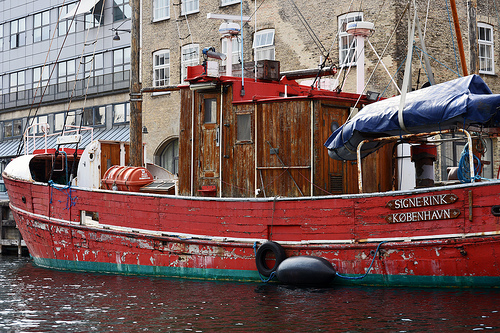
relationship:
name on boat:
[385, 193, 459, 210] [2, 46, 471, 296]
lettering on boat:
[389, 206, 455, 224] [0, 58, 499, 270]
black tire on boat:
[254, 240, 287, 278] [0, 58, 499, 270]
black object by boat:
[276, 255, 337, 288] [0, 58, 499, 270]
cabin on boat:
[177, 59, 396, 197] [0, 58, 499, 270]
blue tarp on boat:
[326, 70, 497, 160] [0, 58, 499, 270]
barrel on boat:
[99, 162, 153, 184] [0, 58, 499, 270]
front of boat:
[7, 149, 44, 175] [0, 58, 499, 270]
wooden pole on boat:
[128, 0, 145, 167] [0, 58, 499, 270]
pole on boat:
[349, 39, 371, 95] [2, 46, 471, 296]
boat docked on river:
[2, 47, 499, 290] [3, 253, 498, 331]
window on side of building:
[11, 19, 24, 54] [0, 1, 131, 209]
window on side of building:
[31, 8, 49, 41] [0, 1, 131, 209]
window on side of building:
[58, 3, 78, 36] [0, 1, 131, 209]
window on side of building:
[8, 70, 25, 103] [2, 5, 128, 162]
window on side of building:
[28, 65, 55, 101] [0, 1, 131, 209]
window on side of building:
[55, 56, 73, 91] [0, 1, 134, 136]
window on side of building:
[85, 50, 102, 93] [0, 0, 130, 111]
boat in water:
[2, 47, 499, 290] [5, 253, 499, 331]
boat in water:
[2, 46, 471, 296] [5, 253, 499, 331]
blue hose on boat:
[451, 141, 482, 184] [0, 58, 499, 270]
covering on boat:
[320, 70, 498, 161] [2, 46, 471, 296]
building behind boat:
[2, 0, 499, 176] [2, 46, 471, 296]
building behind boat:
[2, 5, 128, 162] [2, 47, 499, 290]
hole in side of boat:
[15, 190, 32, 214] [2, 46, 471, 296]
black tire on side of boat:
[252, 240, 288, 284] [4, 9, 466, 287]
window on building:
[339, 10, 367, 64] [141, 1, 441, 81]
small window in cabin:
[228, 110, 255, 144] [169, 65, 394, 195]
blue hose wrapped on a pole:
[451, 141, 473, 181] [454, 137, 483, 183]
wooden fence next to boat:
[0, 220, 31, 254] [2, 46, 471, 296]